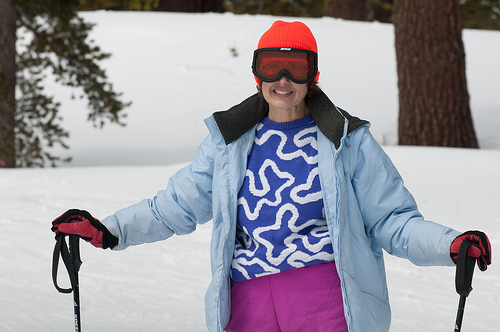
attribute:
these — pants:
[226, 281, 330, 330]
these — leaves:
[67, 36, 78, 48]